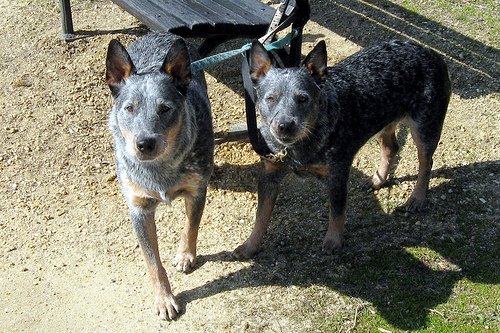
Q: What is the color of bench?
A: Black.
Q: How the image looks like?
A: Good.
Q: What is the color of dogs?
A: Grey.